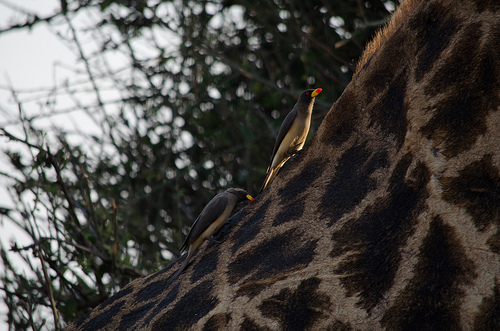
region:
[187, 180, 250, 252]
a bird on the back of a giraffe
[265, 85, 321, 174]
a bird on the back of a giraffe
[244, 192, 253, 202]
the orange beak of the bird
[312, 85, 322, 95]
the orange beak of the bird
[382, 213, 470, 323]
the brown spot of the giraffe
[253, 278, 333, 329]
the brown spot of the giraffe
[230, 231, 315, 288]
the brown spot of the giraffe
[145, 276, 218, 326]
the brown spot of the giraffe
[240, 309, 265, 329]
the brown spot of the giraffe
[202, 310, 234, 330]
the brown spot of the giraffe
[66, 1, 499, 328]
A giraffe has brown spots.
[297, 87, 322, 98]
A bird head with a beak.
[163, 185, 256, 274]
A bird is pecking on a giraffe.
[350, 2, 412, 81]
Sun is shining on some hair.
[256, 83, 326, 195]
One side of the bird has sun shining on it.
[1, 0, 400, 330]
Branches have some green and are blurry.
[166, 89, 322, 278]
Two birds have black wings.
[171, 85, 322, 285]
Two birds have yellow and red beaks.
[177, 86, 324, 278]
Two birds with gray breasts and one has a red eye.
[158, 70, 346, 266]
two birds that are perched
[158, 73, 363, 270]
birds on a giraffe's neck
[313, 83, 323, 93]
small orange beak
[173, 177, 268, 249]
black and white bird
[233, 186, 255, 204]
head is bent down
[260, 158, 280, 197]
feathers on the tail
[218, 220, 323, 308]
dark spot on the skin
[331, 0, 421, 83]
short hair along the neck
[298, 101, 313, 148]
light shining on the bird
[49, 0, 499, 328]
dark spots along the neck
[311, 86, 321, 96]
The yellow and red beak of a bird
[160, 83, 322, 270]
Two black birds on the back of a giraffe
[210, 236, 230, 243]
A bird's little foot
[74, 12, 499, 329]
The back of a giraffe's neck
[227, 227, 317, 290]
The brown spot on a giraffe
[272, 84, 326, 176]
Sunlight shining on a bird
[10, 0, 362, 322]
Tree branches behind the giraffe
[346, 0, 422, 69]
The hair of a giraffe's mane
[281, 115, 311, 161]
The white feathers of a bird's belly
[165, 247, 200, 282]
A bird's tail feathers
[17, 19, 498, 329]
a black and white giraffe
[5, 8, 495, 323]
a close up of an animal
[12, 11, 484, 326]
a scene outside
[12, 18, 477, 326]
a scene during the day time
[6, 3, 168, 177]
a white sky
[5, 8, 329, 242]
a green tree branches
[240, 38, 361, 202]
a bird on top of a giraffe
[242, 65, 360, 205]
a white and black bird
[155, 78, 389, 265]
two birds on a giraffe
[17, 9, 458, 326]
some animals in photo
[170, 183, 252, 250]
A gray and black bird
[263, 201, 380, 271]
And with brown spots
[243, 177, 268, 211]
A bird with a orange and yellow Beale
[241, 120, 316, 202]
A bird on one foot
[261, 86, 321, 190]
the bird is standing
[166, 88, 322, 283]
the two birds are together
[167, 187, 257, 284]
the bird has a beak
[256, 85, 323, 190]
the bird's beak is yellow and red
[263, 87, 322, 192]
the bird is standing up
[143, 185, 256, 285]
the bird is sitting down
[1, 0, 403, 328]
the branches behind the birds